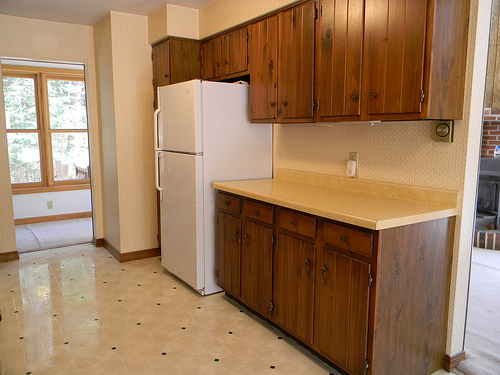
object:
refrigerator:
[151, 78, 273, 297]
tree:
[4, 78, 36, 179]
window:
[0, 71, 88, 189]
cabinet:
[247, 3, 312, 124]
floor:
[0, 243, 93, 375]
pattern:
[158, 342, 223, 374]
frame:
[1, 65, 93, 196]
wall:
[478, 108, 499, 158]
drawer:
[319, 221, 373, 263]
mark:
[158, 351, 166, 357]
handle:
[348, 92, 356, 100]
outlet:
[343, 156, 357, 178]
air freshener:
[344, 159, 358, 176]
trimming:
[118, 247, 160, 264]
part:
[17, 335, 25, 340]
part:
[96, 238, 104, 247]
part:
[48, 80, 88, 132]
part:
[151, 108, 159, 151]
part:
[351, 93, 358, 100]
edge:
[194, 78, 203, 292]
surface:
[211, 177, 454, 223]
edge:
[374, 207, 462, 232]